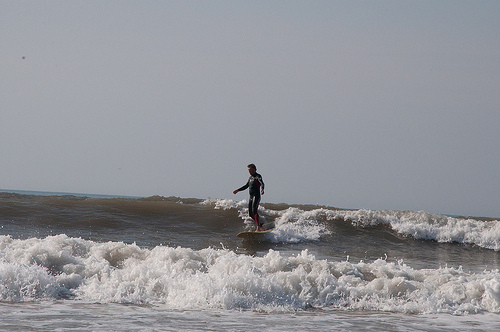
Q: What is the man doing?
A: Surfing.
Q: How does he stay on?
A: Balance.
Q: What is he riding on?
A: Surfboard.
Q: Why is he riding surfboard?
A: Entertainment.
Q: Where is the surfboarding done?
A: Water.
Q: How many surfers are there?
A: One.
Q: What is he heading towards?
A: Beach.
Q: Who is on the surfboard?
A: Man.